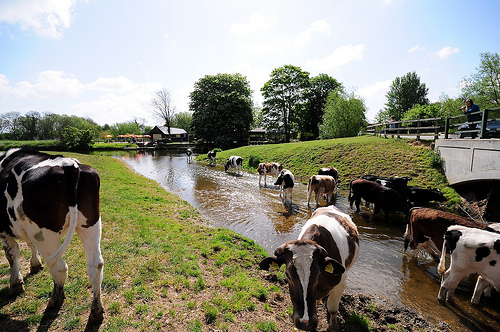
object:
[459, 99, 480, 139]
man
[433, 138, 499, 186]
bridge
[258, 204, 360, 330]
cow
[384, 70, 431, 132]
tree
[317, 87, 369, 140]
tree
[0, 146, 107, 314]
cow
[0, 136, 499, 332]
grass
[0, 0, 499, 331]
background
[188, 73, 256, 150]
leaves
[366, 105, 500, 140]
railing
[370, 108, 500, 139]
fence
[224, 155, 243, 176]
cow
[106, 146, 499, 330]
water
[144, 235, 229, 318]
patches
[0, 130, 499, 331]
field